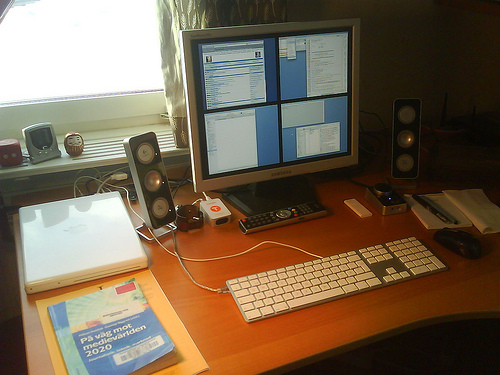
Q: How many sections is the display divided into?
A: Four.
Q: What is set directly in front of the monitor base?
A: Remote control.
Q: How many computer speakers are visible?
A: Two.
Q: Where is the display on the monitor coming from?
A: A laptop.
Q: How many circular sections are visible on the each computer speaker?
A: Three.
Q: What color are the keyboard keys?
A: White.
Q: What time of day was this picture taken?
A: Daytime.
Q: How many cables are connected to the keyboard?
A: Two.